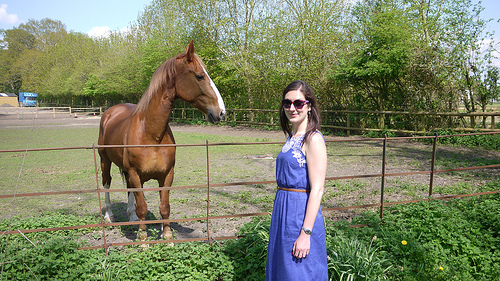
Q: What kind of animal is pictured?
A: A horse.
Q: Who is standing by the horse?
A: A woman.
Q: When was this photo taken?
A: During the daytime.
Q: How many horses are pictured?
A: One.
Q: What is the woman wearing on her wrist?
A: A watch.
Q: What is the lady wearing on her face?
A: Sunglasses.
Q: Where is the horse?
A: In the pasture.